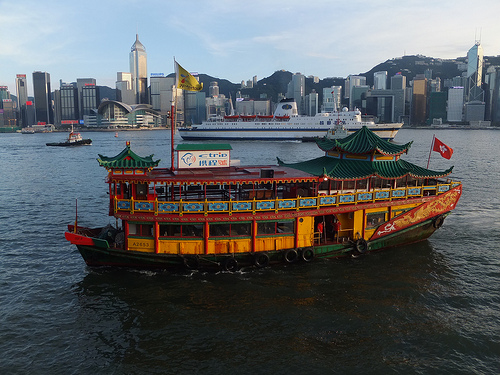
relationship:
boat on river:
[62, 124, 486, 300] [1, 127, 497, 371]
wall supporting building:
[370, 90, 404, 119] [325, 57, 480, 141]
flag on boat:
[425, 136, 457, 163] [63, 102, 462, 273]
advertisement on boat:
[179, 151, 231, 171] [95, 147, 425, 300]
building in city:
[129, 39, 149, 104] [0, 19, 496, 157]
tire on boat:
[218, 255, 243, 275] [62, 124, 486, 300]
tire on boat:
[301, 245, 317, 263] [62, 124, 486, 300]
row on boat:
[202, 246, 319, 274] [62, 124, 486, 300]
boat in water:
[62, 124, 486, 300] [1, 124, 485, 374]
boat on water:
[62, 124, 486, 300] [9, 152, 55, 251]